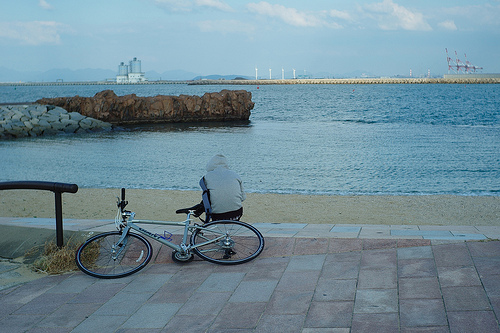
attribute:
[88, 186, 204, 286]
bicycle — black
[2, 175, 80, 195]
railing — black, curved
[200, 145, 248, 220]
person — gray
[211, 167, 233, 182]
jacket — gray hooded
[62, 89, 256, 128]
water — calm, blue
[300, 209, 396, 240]
land — tan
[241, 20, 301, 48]
sky — blue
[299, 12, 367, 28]
clouds — white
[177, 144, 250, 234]
bicyclist — stopped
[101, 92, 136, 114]
rocks — brown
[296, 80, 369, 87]
strips — narrow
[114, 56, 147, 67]
buildings — flat, round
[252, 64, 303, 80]
poles — white, large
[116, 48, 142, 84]
structure — vertical, horizonal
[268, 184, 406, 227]
beach — sandy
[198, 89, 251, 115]
rock — jutting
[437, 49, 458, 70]
terbines — red, white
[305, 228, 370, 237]
path — stone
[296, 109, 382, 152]
body of water — large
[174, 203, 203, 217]
seat — black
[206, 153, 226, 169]
hoodie — white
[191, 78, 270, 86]
pier — stone